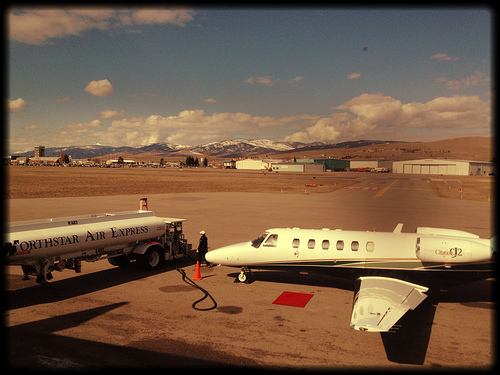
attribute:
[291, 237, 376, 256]
windows — glass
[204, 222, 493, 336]
plane — small, white, parked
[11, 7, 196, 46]
clouds — white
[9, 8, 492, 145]
sky — blue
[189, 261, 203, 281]
cone — orange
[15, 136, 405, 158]
mountains — far away, gray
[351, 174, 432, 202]
lines — yellow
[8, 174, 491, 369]
tarmac — concrete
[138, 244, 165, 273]
tire — round, black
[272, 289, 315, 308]
mat — red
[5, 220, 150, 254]
name — black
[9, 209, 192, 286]
truck — for fuel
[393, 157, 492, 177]
building — white, large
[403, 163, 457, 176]
doors — large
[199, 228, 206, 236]
hat — white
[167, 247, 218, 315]
gas hose — black, long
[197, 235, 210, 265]
clothing — black